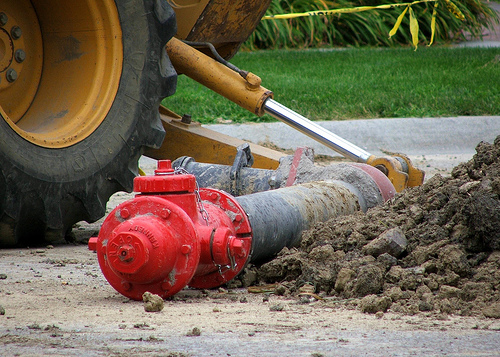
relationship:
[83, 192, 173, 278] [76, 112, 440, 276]
cap on top of hydrant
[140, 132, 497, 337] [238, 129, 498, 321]
rocks mixed in dirt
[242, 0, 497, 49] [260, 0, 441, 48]
foliage behind caution tape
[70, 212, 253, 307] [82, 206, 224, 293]
rocks lying near hydrant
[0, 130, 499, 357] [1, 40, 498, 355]
dirt on ground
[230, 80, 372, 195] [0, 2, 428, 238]
steel on crane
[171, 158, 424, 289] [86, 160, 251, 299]
pipe on hydrant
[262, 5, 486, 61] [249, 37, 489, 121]
plants by grass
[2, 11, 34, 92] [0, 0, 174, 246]
bolts on tire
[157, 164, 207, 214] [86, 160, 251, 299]
chain on hydrant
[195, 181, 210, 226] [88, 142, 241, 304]
chain on hydrant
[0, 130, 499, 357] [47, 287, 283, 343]
dirt by rock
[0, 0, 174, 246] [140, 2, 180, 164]
tire has grooves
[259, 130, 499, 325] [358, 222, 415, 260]
dirt in clump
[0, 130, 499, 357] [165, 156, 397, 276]
dirt on pole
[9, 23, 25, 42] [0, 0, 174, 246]
bolt on tire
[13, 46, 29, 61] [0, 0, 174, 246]
bolt on tire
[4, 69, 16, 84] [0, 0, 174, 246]
bolt on tire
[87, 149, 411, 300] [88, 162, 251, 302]
pipe has cap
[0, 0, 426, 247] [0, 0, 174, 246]
truck has tire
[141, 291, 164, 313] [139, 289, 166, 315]
clump in clump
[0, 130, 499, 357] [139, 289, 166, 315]
dirt in clump